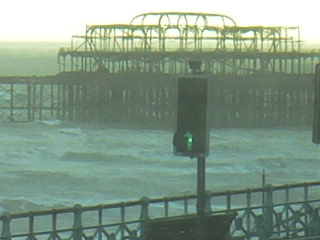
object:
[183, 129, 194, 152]
arrow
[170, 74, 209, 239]
traffic signal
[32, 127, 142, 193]
waves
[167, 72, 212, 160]
light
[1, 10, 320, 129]
bridge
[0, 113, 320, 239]
ocean